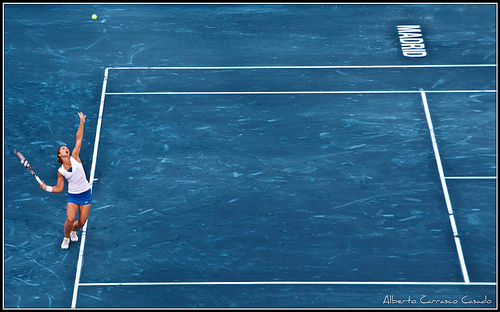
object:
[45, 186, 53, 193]
sweatband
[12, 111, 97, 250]
woman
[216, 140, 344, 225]
ground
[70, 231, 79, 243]
sneaker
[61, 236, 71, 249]
sneaker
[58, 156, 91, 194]
top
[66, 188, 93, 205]
blue shorts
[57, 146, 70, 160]
head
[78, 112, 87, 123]
hand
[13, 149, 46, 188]
racket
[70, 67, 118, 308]
white baseline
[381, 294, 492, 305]
white script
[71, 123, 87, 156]
arm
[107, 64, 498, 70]
white line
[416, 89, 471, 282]
white line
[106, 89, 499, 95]
white line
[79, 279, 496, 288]
white line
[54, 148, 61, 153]
part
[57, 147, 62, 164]
hair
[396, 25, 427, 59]
writing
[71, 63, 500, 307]
court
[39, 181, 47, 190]
hand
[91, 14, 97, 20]
tennis ball